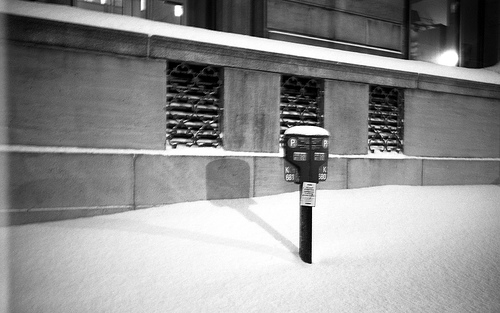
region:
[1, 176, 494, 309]
Street is fill of snow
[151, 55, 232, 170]
Window of basement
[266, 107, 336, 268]
Parking meter in the street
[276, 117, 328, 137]
Snow on top of parking meter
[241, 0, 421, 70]
Window of building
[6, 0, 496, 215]
Building behind parking meter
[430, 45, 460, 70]
Light in the window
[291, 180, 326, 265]
Pole holding the parking meter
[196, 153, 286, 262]
Shadow of parking meter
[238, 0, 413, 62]
Window has a curtain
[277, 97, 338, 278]
black city parking meter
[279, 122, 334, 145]
layer of snow on top of parking meter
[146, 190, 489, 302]
large amount of snow covering ground around parking meter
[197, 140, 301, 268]
shadow cast by parking meter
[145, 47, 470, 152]
vents on city building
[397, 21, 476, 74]
reflection of light on building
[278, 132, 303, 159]
capitol P on parking meter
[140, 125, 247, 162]
snow piled on sill under vents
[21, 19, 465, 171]
cement city building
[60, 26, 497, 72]
pile of snow covering building ledges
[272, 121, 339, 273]
the parking sign is black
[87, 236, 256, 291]
the snow is white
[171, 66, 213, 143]
the windows have bars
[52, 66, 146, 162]
the wall is gray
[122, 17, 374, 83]
the edge has snow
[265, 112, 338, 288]
the sign is in the snow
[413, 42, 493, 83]
the building has a light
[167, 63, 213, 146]
the window is silver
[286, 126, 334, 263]
the sign is a parking sign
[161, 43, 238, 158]
the window is rectangle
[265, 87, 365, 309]
Parking meter in the snow.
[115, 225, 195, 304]
Snow on the ground.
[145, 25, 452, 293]
Building behind parking meter.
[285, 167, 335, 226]
Sign on parking meter.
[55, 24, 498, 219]
Building made of concrete.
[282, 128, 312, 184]
"P" logo on parking meter.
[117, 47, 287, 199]
Decorations on the building.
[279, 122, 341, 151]
Snow on top of parking meter.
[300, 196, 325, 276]
Black pole on parking meter.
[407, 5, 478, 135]
Window on the building.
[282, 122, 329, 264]
Parking meter covered in snow.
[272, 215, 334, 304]
Snow covering the bottom of the meter's pole.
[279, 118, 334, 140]
Top of meter covered with snow.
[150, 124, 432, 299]
Meter in the ground covered with snow.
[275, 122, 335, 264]
Two parking meters on a pole in the snow.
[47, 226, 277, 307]
Snow on the ground.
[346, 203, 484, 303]
Snow covering the ground.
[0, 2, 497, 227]
Commercial business behind the parking meter.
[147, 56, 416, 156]
Three windows with bars.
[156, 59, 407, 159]
Snow on the windows with bars.